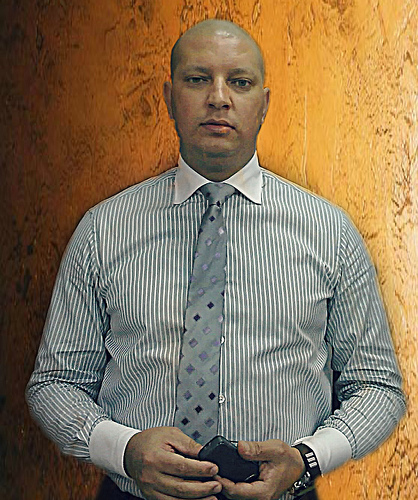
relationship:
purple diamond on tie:
[203, 235, 212, 247] [176, 189, 228, 450]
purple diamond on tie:
[217, 222, 223, 236] [176, 189, 228, 450]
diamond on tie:
[200, 327, 212, 338] [176, 189, 228, 450]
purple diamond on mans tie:
[203, 235, 213, 246] [168, 180, 239, 442]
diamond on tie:
[193, 312, 204, 324] [187, 283, 201, 299]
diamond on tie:
[184, 334, 200, 351] [187, 283, 201, 299]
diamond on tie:
[199, 324, 213, 338] [187, 283, 201, 299]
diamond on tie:
[192, 375, 208, 387] [187, 283, 201, 299]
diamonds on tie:
[210, 275, 217, 283] [176, 182, 239, 445]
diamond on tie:
[200, 327, 212, 338] [176, 182, 239, 445]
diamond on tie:
[192, 312, 200, 323] [176, 182, 239, 445]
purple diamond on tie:
[217, 224, 226, 236] [176, 182, 239, 445]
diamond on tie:
[194, 375, 207, 387] [176, 182, 239, 445]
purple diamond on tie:
[203, 235, 212, 247] [171, 182, 237, 445]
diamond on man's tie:
[200, 327, 212, 338] [172, 182, 240, 444]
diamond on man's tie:
[183, 363, 195, 376] [172, 182, 240, 444]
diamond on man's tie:
[194, 375, 207, 387] [172, 182, 240, 444]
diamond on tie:
[208, 361, 220, 376] [171, 182, 237, 445]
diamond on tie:
[196, 349, 210, 364] [171, 182, 237, 445]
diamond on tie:
[183, 361, 195, 376] [171, 182, 237, 445]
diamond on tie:
[194, 375, 207, 387] [181, 250, 230, 417]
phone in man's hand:
[170, 415, 245, 498] [215, 438, 303, 498]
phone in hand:
[170, 415, 245, 498] [120, 422, 228, 499]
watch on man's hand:
[260, 433, 323, 488] [215, 438, 303, 498]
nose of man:
[199, 74, 246, 122] [25, 17, 404, 497]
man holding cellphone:
[111, 9, 332, 283] [197, 429, 268, 494]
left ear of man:
[262, 84, 272, 122] [25, 17, 404, 497]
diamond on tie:
[193, 248, 198, 258] [171, 182, 237, 445]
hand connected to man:
[114, 415, 225, 493] [102, 18, 398, 395]